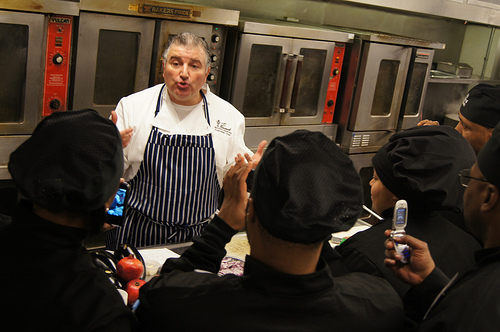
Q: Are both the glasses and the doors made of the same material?
A: Yes, both the glasses and the doors are made of metal.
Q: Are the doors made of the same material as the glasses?
A: Yes, both the doors and the glasses are made of metal.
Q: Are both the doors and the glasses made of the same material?
A: Yes, both the doors and the glasses are made of metal.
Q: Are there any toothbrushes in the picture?
A: No, there are no toothbrushes.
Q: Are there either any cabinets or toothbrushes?
A: No, there are no toothbrushes or cabinets.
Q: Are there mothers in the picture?
A: No, there are no mothers.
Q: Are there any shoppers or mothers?
A: No, there are no mothers or shoppers.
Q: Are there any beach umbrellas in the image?
A: No, there are no beach umbrellas.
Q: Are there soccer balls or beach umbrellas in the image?
A: No, there are no beach umbrellas or soccer balls.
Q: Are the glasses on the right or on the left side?
A: The glasses are on the right of the image.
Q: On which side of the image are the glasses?
A: The glasses are on the right of the image.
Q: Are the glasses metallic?
A: Yes, the glasses are metallic.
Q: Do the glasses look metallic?
A: Yes, the glasses are metallic.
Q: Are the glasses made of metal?
A: Yes, the glasses are made of metal.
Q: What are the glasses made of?
A: The glasses are made of metal.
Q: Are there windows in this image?
A: Yes, there is a window.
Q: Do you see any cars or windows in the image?
A: Yes, there is a window.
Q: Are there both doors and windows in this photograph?
A: Yes, there are both a window and a door.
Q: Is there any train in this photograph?
A: No, there are no trains.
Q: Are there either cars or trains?
A: No, there are no trains or cars.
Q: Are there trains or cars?
A: No, there are no trains or cars.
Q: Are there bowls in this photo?
A: No, there are no bowls.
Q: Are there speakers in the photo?
A: No, there are no speakers.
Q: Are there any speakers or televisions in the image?
A: No, there are no speakers or televisions.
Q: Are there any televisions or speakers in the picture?
A: No, there are no speakers or televisions.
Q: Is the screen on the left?
A: Yes, the screen is on the left of the image.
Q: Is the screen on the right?
A: No, the screen is on the left of the image.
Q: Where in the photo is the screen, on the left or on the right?
A: The screen is on the left of the image.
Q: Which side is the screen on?
A: The screen is on the left of the image.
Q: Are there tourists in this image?
A: No, there are no tourists.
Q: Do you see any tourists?
A: No, there are no tourists.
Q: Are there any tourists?
A: No, there are no tourists.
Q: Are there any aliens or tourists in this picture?
A: No, there are no tourists or aliens.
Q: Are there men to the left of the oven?
A: Yes, there is a man to the left of the oven.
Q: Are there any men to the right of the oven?
A: No, the man is to the left of the oven.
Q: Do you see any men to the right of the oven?
A: No, the man is to the left of the oven.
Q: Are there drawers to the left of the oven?
A: No, there is a man to the left of the oven.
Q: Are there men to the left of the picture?
A: Yes, there is a man to the left of the picture.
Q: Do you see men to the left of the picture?
A: Yes, there is a man to the left of the picture.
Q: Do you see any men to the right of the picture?
A: No, the man is to the left of the picture.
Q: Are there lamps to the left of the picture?
A: No, there is a man to the left of the picture.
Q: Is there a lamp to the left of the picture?
A: No, there is a man to the left of the picture.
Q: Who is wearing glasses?
A: The man is wearing glasses.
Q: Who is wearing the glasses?
A: The man is wearing glasses.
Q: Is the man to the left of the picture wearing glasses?
A: Yes, the man is wearing glasses.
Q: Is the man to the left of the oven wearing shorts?
A: No, the man is wearing glasses.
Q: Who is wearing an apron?
A: The man is wearing an apron.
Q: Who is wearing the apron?
A: The man is wearing an apron.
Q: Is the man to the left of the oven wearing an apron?
A: Yes, the man is wearing an apron.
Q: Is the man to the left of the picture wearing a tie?
A: No, the man is wearing an apron.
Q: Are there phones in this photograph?
A: Yes, there is a phone.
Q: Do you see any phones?
A: Yes, there is a phone.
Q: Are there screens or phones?
A: Yes, there is a phone.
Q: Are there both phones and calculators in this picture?
A: No, there is a phone but no calculators.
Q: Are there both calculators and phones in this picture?
A: No, there is a phone but no calculators.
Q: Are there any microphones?
A: No, there are no microphones.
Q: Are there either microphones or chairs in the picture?
A: No, there are no microphones or chairs.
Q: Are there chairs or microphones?
A: No, there are no microphones or chairs.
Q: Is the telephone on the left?
A: Yes, the telephone is on the left of the image.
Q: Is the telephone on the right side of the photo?
A: No, the telephone is on the left of the image.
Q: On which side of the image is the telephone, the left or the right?
A: The telephone is on the left of the image.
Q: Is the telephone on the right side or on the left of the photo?
A: The telephone is on the left of the image.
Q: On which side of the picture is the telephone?
A: The telephone is on the left of the image.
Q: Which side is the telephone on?
A: The telephone is on the left of the image.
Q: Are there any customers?
A: No, there are no customers.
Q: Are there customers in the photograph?
A: No, there are no customers.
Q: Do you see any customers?
A: No, there are no customers.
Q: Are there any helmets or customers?
A: No, there are no customers or helmets.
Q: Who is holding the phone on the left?
A: The man is holding the telephone.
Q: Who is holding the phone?
A: The man is holding the telephone.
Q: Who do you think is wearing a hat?
A: The man is wearing a hat.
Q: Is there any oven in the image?
A: Yes, there is an oven.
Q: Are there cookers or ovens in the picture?
A: Yes, there is an oven.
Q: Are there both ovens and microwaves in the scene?
A: No, there is an oven but no microwaves.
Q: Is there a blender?
A: No, there are no blenders.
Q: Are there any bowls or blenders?
A: No, there are no blenders or bowls.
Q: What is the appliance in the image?
A: The appliance is an oven.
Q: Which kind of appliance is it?
A: The appliance is an oven.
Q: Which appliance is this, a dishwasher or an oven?
A: This is an oven.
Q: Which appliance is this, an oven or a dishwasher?
A: This is an oven.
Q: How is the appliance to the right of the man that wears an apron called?
A: The appliance is an oven.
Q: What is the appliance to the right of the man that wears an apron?
A: The appliance is an oven.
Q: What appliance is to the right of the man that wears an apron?
A: The appliance is an oven.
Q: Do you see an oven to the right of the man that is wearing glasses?
A: Yes, there is an oven to the right of the man.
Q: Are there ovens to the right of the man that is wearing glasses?
A: Yes, there is an oven to the right of the man.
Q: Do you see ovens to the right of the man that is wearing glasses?
A: Yes, there is an oven to the right of the man.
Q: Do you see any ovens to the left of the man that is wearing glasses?
A: No, the oven is to the right of the man.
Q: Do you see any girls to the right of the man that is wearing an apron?
A: No, there is an oven to the right of the man.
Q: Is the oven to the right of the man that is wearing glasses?
A: Yes, the oven is to the right of the man.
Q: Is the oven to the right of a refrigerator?
A: No, the oven is to the right of the man.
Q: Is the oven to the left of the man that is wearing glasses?
A: No, the oven is to the right of the man.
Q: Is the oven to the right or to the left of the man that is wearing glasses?
A: The oven is to the right of the man.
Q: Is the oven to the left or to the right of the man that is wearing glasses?
A: The oven is to the right of the man.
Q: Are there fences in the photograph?
A: No, there are no fences.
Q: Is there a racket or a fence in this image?
A: No, there are no fences or rackets.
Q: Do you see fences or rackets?
A: No, there are no fences or rackets.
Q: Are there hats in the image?
A: Yes, there is a hat.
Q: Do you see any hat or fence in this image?
A: Yes, there is a hat.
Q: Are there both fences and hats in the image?
A: No, there is a hat but no fences.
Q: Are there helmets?
A: No, there are no helmets.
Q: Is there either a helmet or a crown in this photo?
A: No, there are no helmets or crowns.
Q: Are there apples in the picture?
A: Yes, there is an apple.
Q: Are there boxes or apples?
A: Yes, there is an apple.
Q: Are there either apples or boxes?
A: Yes, there is an apple.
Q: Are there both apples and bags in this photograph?
A: No, there is an apple but no bags.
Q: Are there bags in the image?
A: No, there are no bags.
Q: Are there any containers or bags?
A: No, there are no bags or containers.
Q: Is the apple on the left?
A: Yes, the apple is on the left of the image.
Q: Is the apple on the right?
A: No, the apple is on the left of the image.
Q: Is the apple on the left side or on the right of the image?
A: The apple is on the left of the image.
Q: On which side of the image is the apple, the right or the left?
A: The apple is on the left of the image.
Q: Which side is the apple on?
A: The apple is on the left of the image.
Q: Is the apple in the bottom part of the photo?
A: Yes, the apple is in the bottom of the image.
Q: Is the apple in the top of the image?
A: No, the apple is in the bottom of the image.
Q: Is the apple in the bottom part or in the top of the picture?
A: The apple is in the bottom of the image.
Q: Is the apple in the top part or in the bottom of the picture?
A: The apple is in the bottom of the image.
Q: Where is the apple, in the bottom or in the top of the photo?
A: The apple is in the bottom of the image.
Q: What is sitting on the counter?
A: The apple is sitting on the counter.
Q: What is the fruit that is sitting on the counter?
A: The fruit is an apple.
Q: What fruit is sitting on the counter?
A: The fruit is an apple.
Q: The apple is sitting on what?
A: The apple is sitting on the counter.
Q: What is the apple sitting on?
A: The apple is sitting on the counter.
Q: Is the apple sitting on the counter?
A: Yes, the apple is sitting on the counter.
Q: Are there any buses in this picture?
A: No, there are no buses.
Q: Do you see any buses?
A: No, there are no buses.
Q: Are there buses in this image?
A: No, there are no buses.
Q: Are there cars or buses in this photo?
A: No, there are no buses or cars.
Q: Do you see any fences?
A: No, there are no fences.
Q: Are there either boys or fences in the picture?
A: No, there are no fences or boys.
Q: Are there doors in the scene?
A: Yes, there are doors.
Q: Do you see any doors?
A: Yes, there are doors.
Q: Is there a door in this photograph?
A: Yes, there are doors.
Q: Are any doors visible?
A: Yes, there are doors.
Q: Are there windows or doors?
A: Yes, there are doors.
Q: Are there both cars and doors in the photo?
A: No, there are doors but no cars.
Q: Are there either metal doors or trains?
A: Yes, there are metal doors.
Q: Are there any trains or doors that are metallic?
A: Yes, the doors are metallic.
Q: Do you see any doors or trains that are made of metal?
A: Yes, the doors are made of metal.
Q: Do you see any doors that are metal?
A: Yes, there are metal doors.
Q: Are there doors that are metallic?
A: Yes, there are doors that are metallic.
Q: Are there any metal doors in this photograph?
A: Yes, there are doors that are made of metal.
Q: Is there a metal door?
A: Yes, there are doors that are made of metal.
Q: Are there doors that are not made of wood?
A: Yes, there are doors that are made of metal.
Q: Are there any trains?
A: No, there are no trains.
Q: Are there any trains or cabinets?
A: No, there are no trains or cabinets.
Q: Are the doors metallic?
A: Yes, the doors are metallic.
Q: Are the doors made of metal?
A: Yes, the doors are made of metal.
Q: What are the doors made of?
A: The doors are made of metal.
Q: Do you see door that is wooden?
A: No, there are doors but they are metallic.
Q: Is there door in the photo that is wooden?
A: No, there are doors but they are metallic.